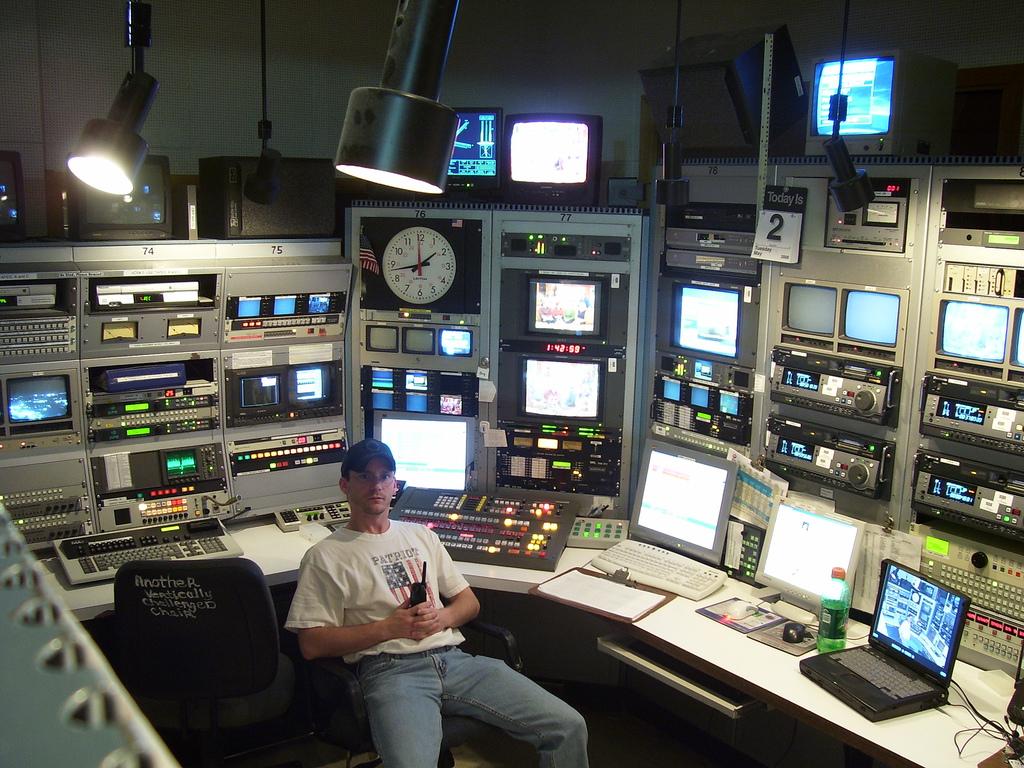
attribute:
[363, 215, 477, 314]
clock — black, white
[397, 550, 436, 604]
radio — black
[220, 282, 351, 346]
screen — small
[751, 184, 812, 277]
number — black 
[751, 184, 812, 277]
calendar — white 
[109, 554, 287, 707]
chair — black 